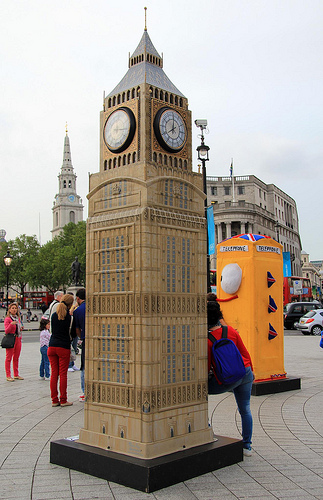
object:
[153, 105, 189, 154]
clock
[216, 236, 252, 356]
face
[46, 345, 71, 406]
pants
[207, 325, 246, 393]
backpack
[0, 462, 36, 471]
tile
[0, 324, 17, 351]
bag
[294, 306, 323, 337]
car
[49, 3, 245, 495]
clock tower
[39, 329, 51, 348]
shirt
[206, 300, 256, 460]
person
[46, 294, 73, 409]
woman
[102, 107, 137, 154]
clock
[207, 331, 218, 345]
straps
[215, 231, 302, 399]
booth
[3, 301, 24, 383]
people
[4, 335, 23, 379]
pants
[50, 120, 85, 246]
building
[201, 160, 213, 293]
pole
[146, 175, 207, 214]
arches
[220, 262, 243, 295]
white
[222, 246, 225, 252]
letters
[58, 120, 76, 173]
steeple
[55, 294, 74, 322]
hair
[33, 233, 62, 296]
trees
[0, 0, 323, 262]
sky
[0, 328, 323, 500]
ground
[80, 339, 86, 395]
pants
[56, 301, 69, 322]
ponytail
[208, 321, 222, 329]
collar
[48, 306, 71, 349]
top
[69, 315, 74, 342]
sleeves